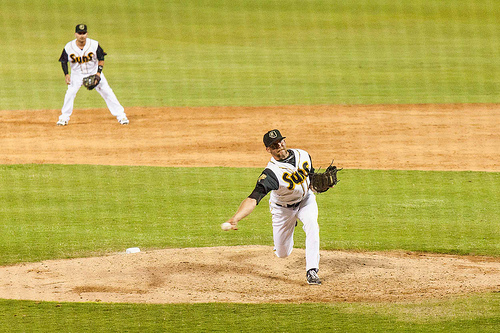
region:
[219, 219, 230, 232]
a white baseball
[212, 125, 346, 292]
a pitcher throwing a ball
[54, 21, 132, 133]
a baseball player on a field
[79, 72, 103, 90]
a base ball glove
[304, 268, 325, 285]
a black and white shoe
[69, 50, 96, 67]
a name on a shirt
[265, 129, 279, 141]
a symbol on a hat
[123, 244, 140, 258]
a white block of caulk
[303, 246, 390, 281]
a shadow on the ground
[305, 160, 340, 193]
a pitchers glove on a ball player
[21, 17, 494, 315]
a baseball game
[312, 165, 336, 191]
the glove of the baseball player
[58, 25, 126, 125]
the player is alert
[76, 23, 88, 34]
this is a cap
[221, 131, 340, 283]
the pitcher is throwing the ball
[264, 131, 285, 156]
the head of the player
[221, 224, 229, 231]
a ball of baseball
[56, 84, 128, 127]
the player has the legs separated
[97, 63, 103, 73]
this is a black band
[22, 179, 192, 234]
a lot of grass in the field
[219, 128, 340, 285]
A pitcher throws the ball.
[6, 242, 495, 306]
The pitcher's mound looks clean.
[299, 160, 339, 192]
The pitcher holds his mitt.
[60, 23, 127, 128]
An outfielder waits for the pitch.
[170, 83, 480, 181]
The outfield is clean dirt.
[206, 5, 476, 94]
Green grass is cut low.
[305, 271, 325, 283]
The pitcher's spike shoes.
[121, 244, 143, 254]
A white box on the pitcher's mound.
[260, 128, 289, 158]
The pitcher has a determined look.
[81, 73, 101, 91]
The outfielder's glove.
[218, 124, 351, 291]
The pitcher is throwing the ball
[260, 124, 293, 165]
Black hat on man's head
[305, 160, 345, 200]
A black leather glove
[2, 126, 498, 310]
Pitcher standing on a pitcher's mound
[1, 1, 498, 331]
Green grass is on the baseball field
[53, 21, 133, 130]
Player is wearing a white and black uniform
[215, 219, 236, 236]
A white round baseball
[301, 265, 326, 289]
A black sneaker with white laces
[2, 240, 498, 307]
The pitcher's mound is round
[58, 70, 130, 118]
The pants are white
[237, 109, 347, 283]
baseball pitcher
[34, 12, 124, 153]
baseball player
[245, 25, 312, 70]
short green and yellow grass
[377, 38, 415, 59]
short green and yellow grass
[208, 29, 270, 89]
short green and yellow grass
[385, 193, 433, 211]
short green and yellow grass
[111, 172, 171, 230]
short green and yellow grass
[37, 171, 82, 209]
short green and yellow grass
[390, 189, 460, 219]
short green and yellow grass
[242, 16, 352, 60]
short green and yellow grass